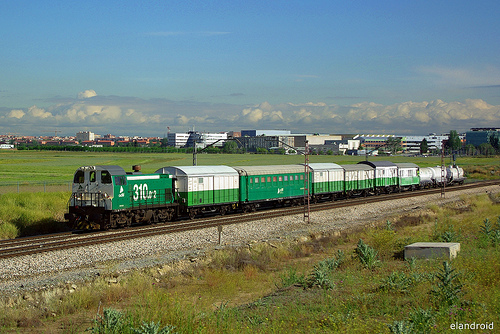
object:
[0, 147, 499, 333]
ground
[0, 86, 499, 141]
clouds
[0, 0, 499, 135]
sky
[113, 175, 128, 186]
window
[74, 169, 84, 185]
window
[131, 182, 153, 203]
310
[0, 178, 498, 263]
railroad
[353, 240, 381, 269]
plants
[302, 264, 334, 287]
plants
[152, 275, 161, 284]
rocks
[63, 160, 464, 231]
train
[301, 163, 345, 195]
train car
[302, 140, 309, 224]
poles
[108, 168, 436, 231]
train`s side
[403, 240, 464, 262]
stone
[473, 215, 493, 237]
grass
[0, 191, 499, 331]
grass field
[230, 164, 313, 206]
car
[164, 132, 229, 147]
buildings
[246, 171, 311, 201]
paint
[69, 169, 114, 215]
back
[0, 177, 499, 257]
tracks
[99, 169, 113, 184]
front windows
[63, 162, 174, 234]
train engine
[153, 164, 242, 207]
car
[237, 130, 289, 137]
buildings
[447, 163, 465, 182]
tanker car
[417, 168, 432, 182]
tanker car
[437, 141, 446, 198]
poles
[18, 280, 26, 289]
gravel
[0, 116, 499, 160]
city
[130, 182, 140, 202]
numbers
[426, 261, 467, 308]
grass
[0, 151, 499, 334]
field